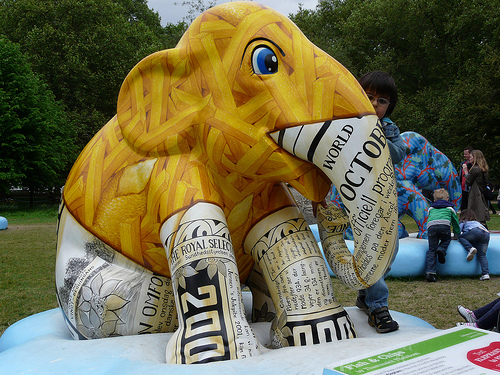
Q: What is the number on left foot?
A: 200.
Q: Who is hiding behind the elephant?
A: The little boy.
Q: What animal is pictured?
A: Elephant.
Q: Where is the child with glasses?
A: Behind the trunk.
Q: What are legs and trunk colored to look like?
A: Newspaper.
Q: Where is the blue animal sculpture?
A: Behind the yellow one.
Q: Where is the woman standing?
A: By the blue sculpture.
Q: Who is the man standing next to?
A: The woman.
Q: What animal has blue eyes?
A: The yellow elephant.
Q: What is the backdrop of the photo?
A: Trees.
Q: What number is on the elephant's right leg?
A: 200.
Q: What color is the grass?
A: Green.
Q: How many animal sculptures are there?
A: Two.